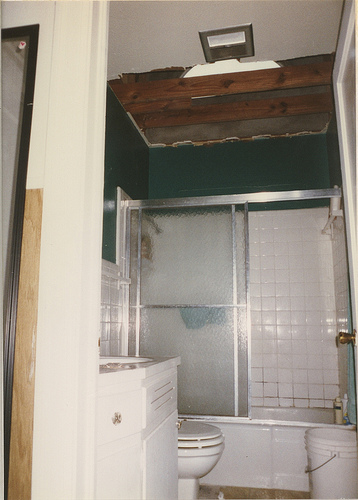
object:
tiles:
[274, 255, 288, 270]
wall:
[101, 139, 342, 410]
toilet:
[177, 432, 223, 498]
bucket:
[305, 427, 357, 500]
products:
[341, 394, 348, 419]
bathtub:
[179, 406, 350, 488]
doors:
[126, 205, 238, 416]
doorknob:
[337, 330, 355, 347]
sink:
[99, 354, 175, 500]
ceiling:
[109, 1, 334, 140]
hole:
[108, 58, 334, 145]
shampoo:
[333, 396, 343, 425]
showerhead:
[140, 211, 164, 236]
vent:
[199, 25, 254, 60]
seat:
[178, 421, 222, 462]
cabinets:
[144, 361, 178, 500]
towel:
[179, 306, 230, 330]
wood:
[120, 76, 334, 136]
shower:
[122, 189, 350, 425]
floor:
[200, 484, 304, 499]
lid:
[178, 421, 222, 440]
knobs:
[111, 412, 122, 426]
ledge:
[177, 413, 353, 431]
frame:
[331, 0, 358, 344]